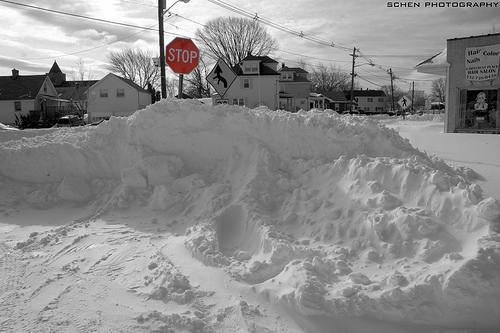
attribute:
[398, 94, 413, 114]
sign — pedestrian crossing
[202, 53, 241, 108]
sign — warning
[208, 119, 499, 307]
sand — heap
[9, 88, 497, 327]
sand — heap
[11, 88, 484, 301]
mound — snow